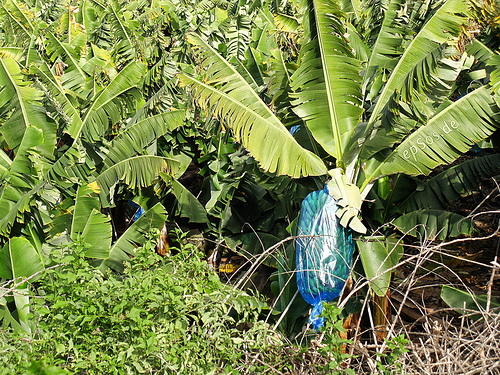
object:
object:
[294, 187, 355, 332]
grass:
[0, 341, 156, 375]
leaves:
[67, 271, 78, 285]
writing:
[402, 119, 461, 163]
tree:
[175, 2, 497, 234]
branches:
[484, 270, 500, 313]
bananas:
[311, 200, 317, 213]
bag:
[294, 187, 354, 334]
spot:
[217, 257, 238, 275]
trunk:
[371, 296, 394, 341]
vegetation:
[1, 0, 499, 334]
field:
[50, 79, 475, 366]